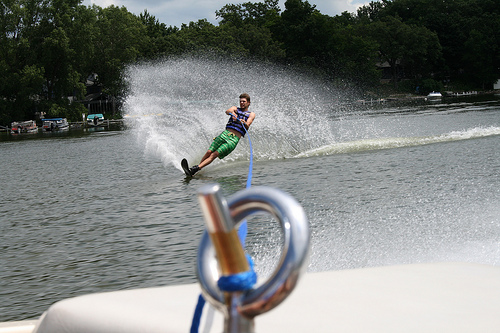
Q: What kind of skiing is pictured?
A: Water skiing.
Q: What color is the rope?
A: Blue.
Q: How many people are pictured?
A: One.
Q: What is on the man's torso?
A: A float coat.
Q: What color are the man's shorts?
A: Green.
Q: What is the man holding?
A: A rope.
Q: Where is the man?
A: On his ski.